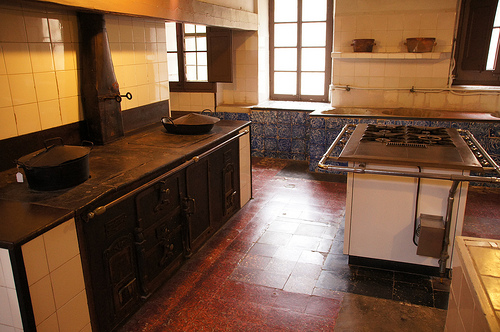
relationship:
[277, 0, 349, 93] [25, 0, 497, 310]
window in a room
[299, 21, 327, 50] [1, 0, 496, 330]
window in room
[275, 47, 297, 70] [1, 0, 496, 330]
window in room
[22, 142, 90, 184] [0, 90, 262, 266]
skillet on counter